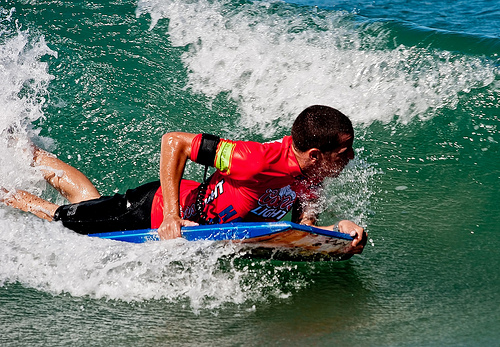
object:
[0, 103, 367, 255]
man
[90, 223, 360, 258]
surfboard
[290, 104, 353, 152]
hair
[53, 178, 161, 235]
shorts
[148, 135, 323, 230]
shirt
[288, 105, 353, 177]
head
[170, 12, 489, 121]
wave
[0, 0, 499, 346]
ocean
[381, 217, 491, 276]
ripples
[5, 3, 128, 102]
water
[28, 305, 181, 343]
ripples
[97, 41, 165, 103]
ripples